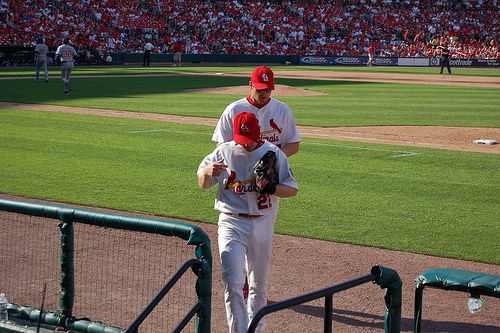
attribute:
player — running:
[180, 109, 323, 330]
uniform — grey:
[191, 144, 298, 330]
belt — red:
[237, 211, 266, 220]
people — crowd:
[391, 25, 416, 42]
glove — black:
[251, 151, 278, 196]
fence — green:
[95, 48, 309, 110]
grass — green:
[7, 107, 187, 211]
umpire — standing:
[428, 33, 460, 76]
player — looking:
[197, 110, 299, 331]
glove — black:
[195, 107, 305, 331]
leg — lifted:
[214, 240, 253, 331]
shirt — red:
[183, 136, 325, 212]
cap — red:
[247, 63, 279, 95]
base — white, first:
[471, 131, 498, 147]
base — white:
[337, 119, 499, 158]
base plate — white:
[474, 138, 497, 147]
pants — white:
[199, 191, 306, 328]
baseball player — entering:
[197, 111, 297, 330]